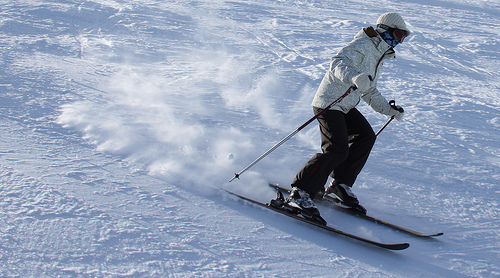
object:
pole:
[226, 74, 374, 183]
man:
[282, 11, 411, 220]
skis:
[215, 179, 443, 251]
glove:
[351, 73, 374, 91]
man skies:
[221, 12, 448, 252]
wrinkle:
[296, 171, 303, 179]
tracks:
[11, 1, 324, 207]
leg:
[294, 110, 348, 194]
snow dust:
[46, 20, 294, 220]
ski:
[220, 10, 441, 252]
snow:
[0, 0, 500, 278]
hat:
[376, 12, 411, 36]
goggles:
[378, 24, 407, 43]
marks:
[244, 24, 317, 76]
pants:
[291, 106, 376, 197]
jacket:
[311, 26, 395, 116]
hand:
[352, 72, 375, 90]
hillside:
[0, 2, 500, 278]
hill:
[0, 8, 497, 275]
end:
[217, 185, 265, 208]